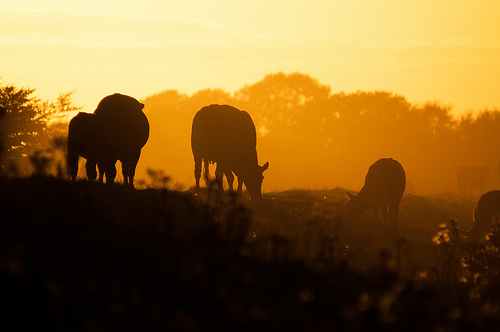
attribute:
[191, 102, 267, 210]
animal — grazign, grazing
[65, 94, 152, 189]
animal — grazing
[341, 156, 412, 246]
animal — grazing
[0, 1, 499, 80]
sky — hazy, golden, yellow, orange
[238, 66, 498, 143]
foliage — yellow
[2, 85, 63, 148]
trees — green, leafy, tall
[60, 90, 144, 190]
cows — grazing, shadowed, eating, standing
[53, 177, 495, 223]
pasture — yellow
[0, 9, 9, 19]
sun — orange, setting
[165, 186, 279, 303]
grass — tall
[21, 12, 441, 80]
light — shining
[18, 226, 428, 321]
bushes — dark